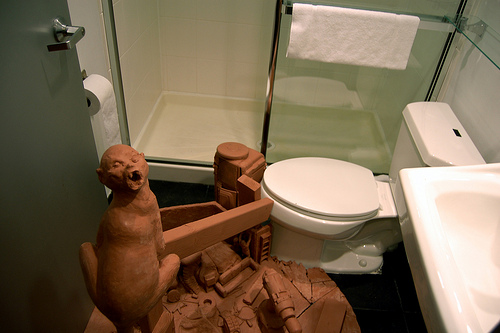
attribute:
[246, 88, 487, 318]
tiolet — white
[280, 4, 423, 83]
towel — white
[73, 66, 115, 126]
paper — white, tissue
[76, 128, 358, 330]
statue — brown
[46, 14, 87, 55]
handle — door, silver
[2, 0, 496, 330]
room — bath, white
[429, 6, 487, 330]
wall — white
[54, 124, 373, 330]
fixture — clay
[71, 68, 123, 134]
paper — toilet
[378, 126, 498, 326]
sink — white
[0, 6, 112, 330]
door — grey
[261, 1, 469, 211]
door — glass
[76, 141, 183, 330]
cat creature — strange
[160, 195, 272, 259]
beam — wooden, small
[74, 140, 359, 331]
carving — reddish brown, hand crafted